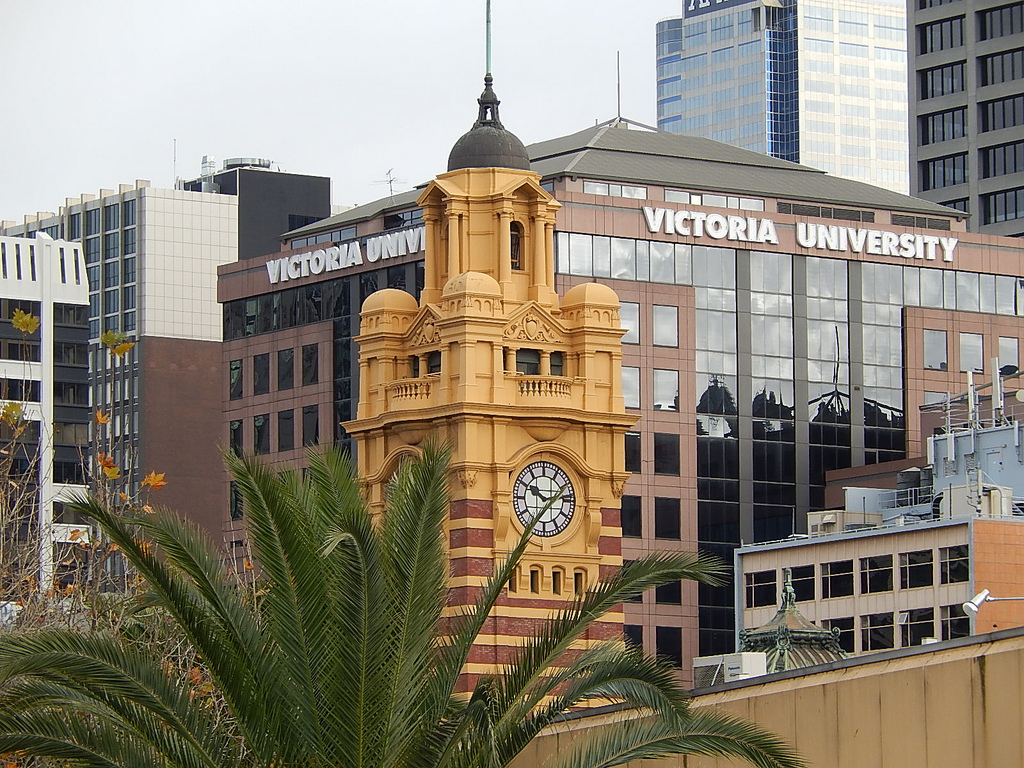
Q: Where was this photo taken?
A: Outside of Victoria University.